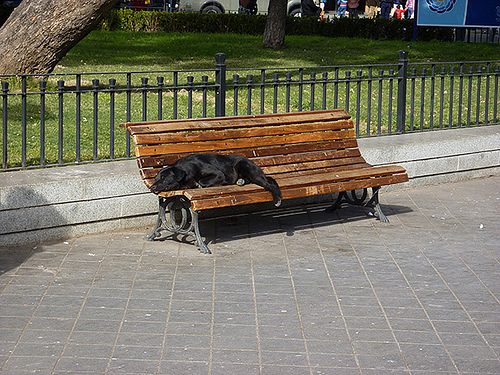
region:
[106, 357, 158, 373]
grey stone on ground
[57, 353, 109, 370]
grey stone on ground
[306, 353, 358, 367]
grey stone on ground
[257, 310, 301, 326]
grey stone on ground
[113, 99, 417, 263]
wooden bench on sidewalk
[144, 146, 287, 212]
black dog sleeping on brown bench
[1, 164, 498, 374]
tiled concrete paved sidewalk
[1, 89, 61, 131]
shadow on grass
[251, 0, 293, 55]
brown tree trunk inside fenced enclosure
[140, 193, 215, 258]
black metal legs of bench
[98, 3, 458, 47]
line of short bushes lining black metal fence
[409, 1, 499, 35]
light and dark blue banner on metal fence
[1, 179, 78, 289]
shadow on pavment and wall foundation of fence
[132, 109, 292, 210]
black dog sleeping on wooden bench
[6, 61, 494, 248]
black railing over stone partition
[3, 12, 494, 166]
grassy area bordered by bushes on other side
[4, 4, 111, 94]
tree trunk leaning heavily to one side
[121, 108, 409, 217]
deep brown slats forming curving bench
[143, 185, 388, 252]
round and flared metal supports under bench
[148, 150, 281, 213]
leg hanging off of bench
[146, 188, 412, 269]
stained ground in front of bench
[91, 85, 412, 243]
bench on the ground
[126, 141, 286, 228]
black dog on bench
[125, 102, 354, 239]
dog laying down on bench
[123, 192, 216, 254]
legs of the bench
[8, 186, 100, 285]
shadow near the bench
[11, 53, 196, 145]
fence behind the bench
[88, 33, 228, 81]
grass on the ground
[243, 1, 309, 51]
trunk of a tree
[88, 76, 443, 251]
this is a bench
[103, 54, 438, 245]
the bench is wooden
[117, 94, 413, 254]
the bench is brown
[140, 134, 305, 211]
this is a dog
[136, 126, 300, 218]
the dog is black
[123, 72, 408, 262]
the dog is laying down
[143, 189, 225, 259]
iron leg on the bench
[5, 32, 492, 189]
black fence behind bench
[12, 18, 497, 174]
grassy area behind fence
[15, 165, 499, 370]
cement tile on ground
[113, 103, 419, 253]
bench is color brown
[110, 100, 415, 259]
cat sits on a bench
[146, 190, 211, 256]
left leg of bench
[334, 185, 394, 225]
right leg of bench